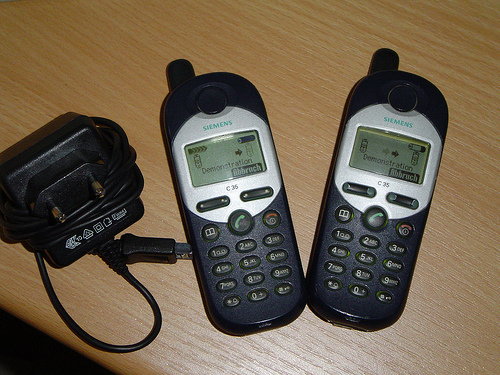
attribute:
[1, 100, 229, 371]
cable — black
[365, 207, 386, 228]
call sign — blue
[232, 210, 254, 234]
power buttons — red, green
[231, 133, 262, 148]
battery — full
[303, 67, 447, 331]
phone — black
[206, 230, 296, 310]
buttons — black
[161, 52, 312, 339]
phone — black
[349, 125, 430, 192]
screen — small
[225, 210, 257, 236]
call button — green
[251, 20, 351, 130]
surface — brown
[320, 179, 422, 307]
buttons — black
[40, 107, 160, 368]
charging unit — black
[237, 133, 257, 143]
battery — fully charged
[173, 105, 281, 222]
frame — grey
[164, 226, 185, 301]
adapter — silver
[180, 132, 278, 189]
screen — small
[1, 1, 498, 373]
table — brown, light brown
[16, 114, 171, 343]
battery — charged, full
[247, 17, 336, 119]
surface — wooden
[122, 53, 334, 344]
phone — old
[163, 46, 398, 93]
antennas — black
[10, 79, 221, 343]
charger — black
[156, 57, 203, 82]
antenna — small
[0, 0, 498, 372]
surface — wooden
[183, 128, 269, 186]
screen — small, LCD